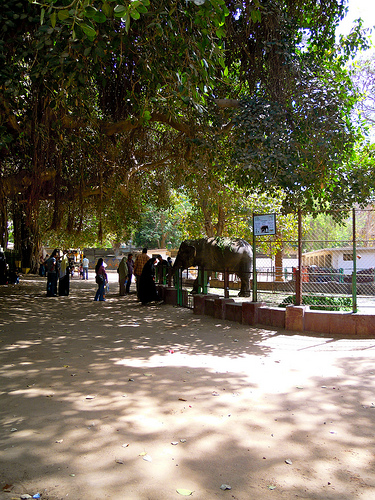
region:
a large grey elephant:
[166, 238, 249, 298]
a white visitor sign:
[252, 214, 275, 234]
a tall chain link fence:
[251, 211, 373, 310]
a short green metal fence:
[151, 264, 251, 306]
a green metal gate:
[176, 268, 202, 309]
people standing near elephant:
[117, 237, 252, 305]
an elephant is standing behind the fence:
[166, 237, 259, 302]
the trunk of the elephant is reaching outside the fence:
[166, 235, 252, 297]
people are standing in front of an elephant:
[118, 236, 254, 305]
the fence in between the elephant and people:
[118, 237, 373, 336]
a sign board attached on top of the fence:
[251, 211, 374, 318]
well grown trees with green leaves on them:
[3, 157, 369, 287]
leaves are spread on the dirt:
[3, 299, 374, 498]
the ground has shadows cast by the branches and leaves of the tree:
[4, 153, 372, 493]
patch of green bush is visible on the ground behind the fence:
[256, 212, 369, 308]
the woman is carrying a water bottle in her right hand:
[93, 258, 110, 300]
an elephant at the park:
[175, 232, 260, 300]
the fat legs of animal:
[194, 268, 252, 300]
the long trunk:
[158, 257, 179, 280]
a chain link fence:
[249, 198, 371, 313]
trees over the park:
[1, 5, 372, 269]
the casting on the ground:
[106, 318, 372, 476]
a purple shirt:
[90, 266, 111, 281]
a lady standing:
[86, 253, 109, 308]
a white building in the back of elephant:
[297, 240, 372, 288]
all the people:
[0, 251, 177, 312]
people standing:
[34, 231, 164, 311]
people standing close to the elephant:
[112, 233, 259, 316]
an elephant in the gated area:
[165, 233, 258, 298]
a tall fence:
[248, 204, 374, 336]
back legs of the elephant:
[237, 274, 254, 298]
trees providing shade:
[3, 20, 374, 279]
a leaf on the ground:
[171, 486, 198, 496]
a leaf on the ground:
[282, 455, 294, 466]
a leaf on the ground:
[83, 391, 95, 400]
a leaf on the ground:
[9, 425, 18, 433]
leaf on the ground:
[219, 482, 234, 492]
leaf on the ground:
[173, 486, 197, 496]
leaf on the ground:
[284, 454, 294, 470]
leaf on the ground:
[267, 483, 277, 490]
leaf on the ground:
[171, 440, 179, 447]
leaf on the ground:
[177, 436, 189, 442]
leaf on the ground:
[53, 437, 67, 445]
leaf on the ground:
[83, 393, 94, 401]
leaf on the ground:
[125, 376, 135, 384]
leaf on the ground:
[295, 382, 303, 392]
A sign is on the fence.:
[252, 214, 278, 233]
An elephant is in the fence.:
[166, 233, 251, 295]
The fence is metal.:
[248, 210, 372, 304]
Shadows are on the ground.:
[180, 442, 273, 495]